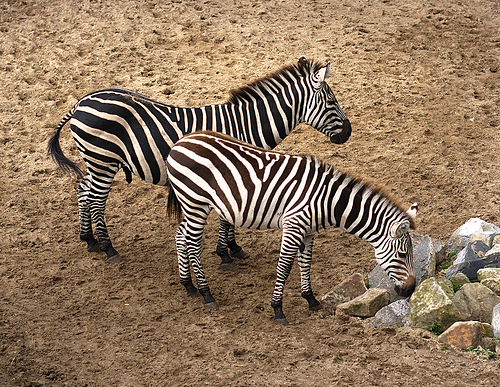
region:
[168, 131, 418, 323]
An brown and white zebra smelling rocks.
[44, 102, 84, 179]
A black and white tail of a black and white zebra.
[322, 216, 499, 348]
A pile of rocks a zebra is smelling.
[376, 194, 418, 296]
Head of a brown and white zebra.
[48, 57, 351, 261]
A black and white zebra.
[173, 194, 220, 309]
Set of back legs on a brown and white zebra.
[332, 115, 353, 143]
Black nose and mouth area of a black and white zebra.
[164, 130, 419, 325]
A brown and white zebra with it's head down.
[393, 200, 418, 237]
Two ears on a zebra's head that is mostly brown and white.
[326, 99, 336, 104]
Black eye on a dark black and white zebra.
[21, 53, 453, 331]
There are two zebras.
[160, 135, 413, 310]
The zebra is light black and white.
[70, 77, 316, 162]
The zebra is dark black and white.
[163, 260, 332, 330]
The feet are black.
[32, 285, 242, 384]
The ground is dirt covered.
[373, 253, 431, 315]
The zebra is smelling rocks.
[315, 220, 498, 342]
Rocks on the ground.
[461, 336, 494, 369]
Grass under a rock.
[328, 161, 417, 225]
The mane is brown.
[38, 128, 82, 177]
The tail is black.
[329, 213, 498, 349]
Pile of large rocks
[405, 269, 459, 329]
moss is growing on rocks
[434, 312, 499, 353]
rock colored like red clay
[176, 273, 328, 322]
hooves are all black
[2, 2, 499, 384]
ground covered in dried grass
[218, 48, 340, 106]
zebra mane is striped too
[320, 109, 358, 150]
zebra has a black nose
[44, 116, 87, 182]
long black hair on the tail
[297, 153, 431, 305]
zebra has head bent down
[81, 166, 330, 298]
narrower stripes are on the legs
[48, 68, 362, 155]
MALE ZEBRA STANDING IN DIRT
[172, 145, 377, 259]
ZEBRA STANDING IN DIRT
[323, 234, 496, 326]
PILE OF ROCKS ON RIGHT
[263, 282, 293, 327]
BLACK HOOF OF ZEBRA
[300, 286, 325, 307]
BLACK HOOF OF ZEBRA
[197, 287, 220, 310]
BLACK HOOF OF ZEBRA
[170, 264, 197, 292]
BLACK HOOF OF ZEBRA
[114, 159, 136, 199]
PENIS OF ZEBRA ON LEFT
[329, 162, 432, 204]
STIFF MANE ON ZEBRA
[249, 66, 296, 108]
STIFF MANE ON ZEBRA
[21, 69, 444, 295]
There are two zebras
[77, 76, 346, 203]
The zebras are white and black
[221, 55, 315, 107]
The zebra has a brown mane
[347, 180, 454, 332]
He is looking at the rocks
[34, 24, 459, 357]
They are standing in a field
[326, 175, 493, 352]
There is a pile of rocks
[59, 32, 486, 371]
there is no grass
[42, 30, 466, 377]
The ground is brown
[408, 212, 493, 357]
there are many kinds of rocks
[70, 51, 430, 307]
zebras next to each other